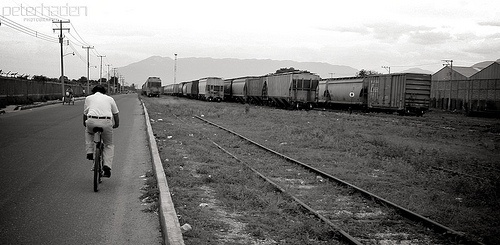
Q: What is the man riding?
A: A bike.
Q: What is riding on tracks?
A: A train.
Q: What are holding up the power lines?
A: Poles.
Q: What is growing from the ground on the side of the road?
A: Grass.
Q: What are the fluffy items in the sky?
A: Clouds.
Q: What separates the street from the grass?
A: A curb.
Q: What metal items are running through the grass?
A: Train tracks.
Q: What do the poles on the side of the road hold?
A: Power lines.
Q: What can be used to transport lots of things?
A: Trains.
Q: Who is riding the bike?
A: A man.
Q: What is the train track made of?
A: Iron.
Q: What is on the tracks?
A: Trains.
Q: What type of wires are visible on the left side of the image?
A: Electric wires.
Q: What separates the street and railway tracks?
A: Cement curb.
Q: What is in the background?
A: Mountains.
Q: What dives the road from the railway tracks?
A: Curb.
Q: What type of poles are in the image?
A: Utility lines poles.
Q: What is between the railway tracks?
A: Litter and overgrown grass.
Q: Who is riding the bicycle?
A: A man.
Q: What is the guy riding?
A: Bike.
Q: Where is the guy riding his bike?
A: Train Yard.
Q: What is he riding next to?
A: Train tracks.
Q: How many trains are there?
A: 4.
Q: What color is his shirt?
A: White.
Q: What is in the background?
A: Mountains.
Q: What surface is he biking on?
A: Asphalt.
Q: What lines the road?
A: Curb.